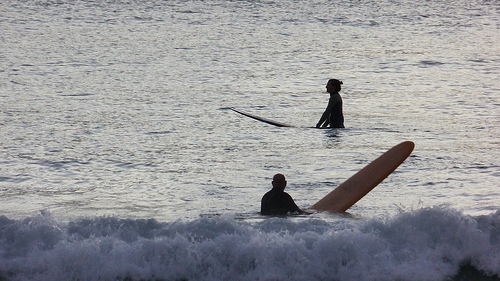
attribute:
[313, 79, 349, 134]
surfer — female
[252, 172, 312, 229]
surfer — male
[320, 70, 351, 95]
hair — up, brunette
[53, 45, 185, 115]
water — calm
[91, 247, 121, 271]
froth — white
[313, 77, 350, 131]
person — female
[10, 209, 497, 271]
wave — frothy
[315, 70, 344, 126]
person — female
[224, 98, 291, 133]
board — for surfing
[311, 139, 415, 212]
board — for surfing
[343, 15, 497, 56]
light — from the sky